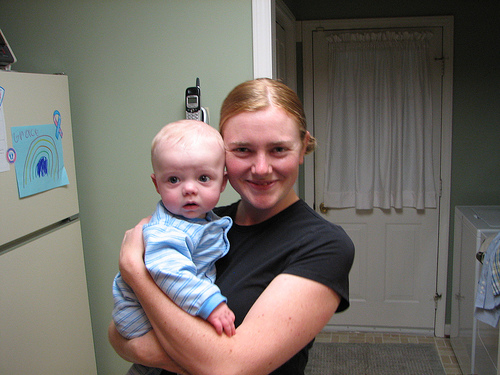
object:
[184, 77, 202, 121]
telephone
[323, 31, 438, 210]
curtain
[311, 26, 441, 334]
door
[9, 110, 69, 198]
drawing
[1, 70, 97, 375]
fridge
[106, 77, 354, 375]
woman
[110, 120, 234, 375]
baby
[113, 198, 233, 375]
onesie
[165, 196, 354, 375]
shirt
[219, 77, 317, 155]
hair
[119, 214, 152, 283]
hand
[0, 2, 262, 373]
wall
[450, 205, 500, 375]
washer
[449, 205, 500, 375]
dryer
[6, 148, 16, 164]
magnet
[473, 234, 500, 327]
cloth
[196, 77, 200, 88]
aentenna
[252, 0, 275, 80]
strip